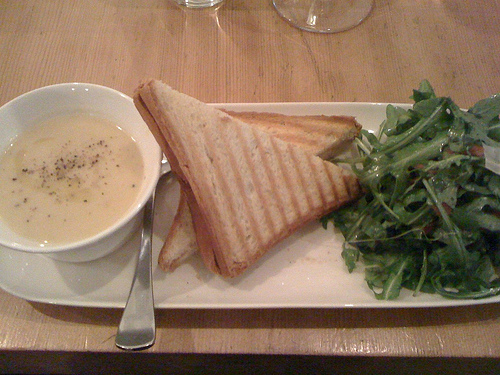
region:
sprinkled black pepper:
[10, 133, 115, 221]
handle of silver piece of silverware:
[115, 187, 160, 346]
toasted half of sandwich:
[133, 78, 355, 275]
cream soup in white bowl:
[1, 82, 159, 266]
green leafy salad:
[319, 83, 499, 298]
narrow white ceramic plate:
[1, 94, 498, 310]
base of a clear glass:
[270, 0, 376, 34]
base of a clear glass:
[175, 1, 225, 11]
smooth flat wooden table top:
[2, 3, 498, 370]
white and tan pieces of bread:
[148, 82, 311, 257]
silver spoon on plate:
[114, 101, 180, 357]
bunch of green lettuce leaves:
[383, 77, 486, 284]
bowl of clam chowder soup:
[19, 125, 124, 221]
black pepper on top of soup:
[33, 160, 131, 199]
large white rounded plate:
[40, 76, 497, 291]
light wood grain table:
[211, 51, 444, 103]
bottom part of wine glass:
[275, 2, 380, 38]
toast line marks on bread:
[205, 177, 320, 248]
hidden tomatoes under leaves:
[433, 144, 470, 208]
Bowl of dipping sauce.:
[2, 92, 147, 247]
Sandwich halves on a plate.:
[136, 75, 369, 273]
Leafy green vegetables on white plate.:
[356, 91, 498, 313]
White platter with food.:
[1, 95, 497, 309]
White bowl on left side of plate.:
[0, 85, 161, 266]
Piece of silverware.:
[117, 121, 175, 347]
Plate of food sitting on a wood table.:
[2, 13, 499, 359]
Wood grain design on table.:
[41, 16, 273, 74]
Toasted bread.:
[144, 79, 364, 274]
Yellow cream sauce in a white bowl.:
[3, 83, 150, 265]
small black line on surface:
[287, 32, 352, 72]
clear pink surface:
[42, 6, 255, 81]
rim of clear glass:
[255, 7, 384, 49]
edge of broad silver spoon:
[107, 320, 167, 343]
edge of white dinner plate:
[233, 292, 350, 329]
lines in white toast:
[220, 173, 299, 215]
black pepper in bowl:
[27, 148, 84, 187]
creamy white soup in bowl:
[10, 136, 123, 238]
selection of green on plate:
[333, 75, 499, 273]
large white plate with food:
[20, 44, 497, 335]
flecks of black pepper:
[13, 139, 119, 211]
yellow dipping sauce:
[1, 106, 146, 241]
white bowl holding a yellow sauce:
[0, 65, 166, 275]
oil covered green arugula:
[334, 58, 499, 296]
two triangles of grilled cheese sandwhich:
[129, 76, 369, 291]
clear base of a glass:
[263, 0, 388, 45]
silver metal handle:
[112, 239, 160, 357]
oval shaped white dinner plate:
[0, 66, 498, 334]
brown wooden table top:
[30, 14, 156, 69]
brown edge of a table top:
[247, 337, 477, 374]